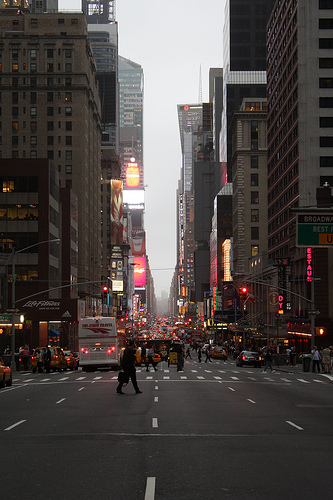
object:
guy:
[117, 341, 143, 396]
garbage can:
[303, 352, 315, 373]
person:
[116, 340, 142, 395]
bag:
[118, 371, 129, 383]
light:
[19, 312, 24, 322]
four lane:
[0, 379, 332, 499]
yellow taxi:
[210, 344, 227, 358]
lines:
[142, 476, 157, 498]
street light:
[242, 286, 248, 294]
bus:
[77, 316, 118, 364]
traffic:
[131, 316, 262, 366]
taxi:
[62, 352, 78, 370]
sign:
[133, 256, 147, 288]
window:
[250, 101, 254, 110]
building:
[0, 156, 62, 318]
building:
[118, 55, 144, 228]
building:
[231, 97, 268, 326]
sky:
[58, 0, 224, 300]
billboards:
[110, 177, 124, 246]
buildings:
[192, 67, 223, 302]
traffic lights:
[104, 284, 106, 289]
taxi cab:
[134, 346, 161, 368]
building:
[60, 185, 79, 297]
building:
[266, 0, 333, 320]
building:
[209, 183, 234, 290]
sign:
[306, 248, 312, 280]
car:
[233, 349, 263, 367]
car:
[206, 345, 228, 359]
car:
[49, 349, 65, 372]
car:
[189, 339, 204, 351]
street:
[0, 334, 332, 499]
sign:
[296, 212, 332, 248]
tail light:
[108, 349, 110, 353]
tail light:
[111, 345, 114, 349]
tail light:
[85, 350, 88, 353]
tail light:
[80, 347, 83, 350]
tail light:
[94, 343, 100, 345]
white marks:
[59, 375, 71, 381]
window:
[123, 119, 135, 124]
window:
[123, 114, 135, 118]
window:
[116, 84, 120, 89]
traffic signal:
[18, 312, 25, 324]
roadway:
[0, 345, 332, 499]